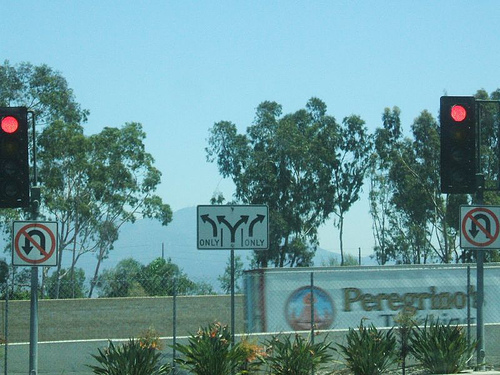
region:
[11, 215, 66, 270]
No u turn sign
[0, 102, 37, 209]
A red stop light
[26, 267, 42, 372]
Metal sign post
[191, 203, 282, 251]
Sign with four direction arrows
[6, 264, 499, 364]
A chain link fence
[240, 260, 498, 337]
A white tractor trailer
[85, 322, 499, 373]
Five shrubs in front of a fence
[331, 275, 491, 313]
The word Peregrino's on a trailer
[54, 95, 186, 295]
Green trees on the other side of the road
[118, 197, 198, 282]
Mountains in the far distance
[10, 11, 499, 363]
stoplights and street signs by wall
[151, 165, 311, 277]
street sign with arrows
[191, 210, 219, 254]
left arrow on sign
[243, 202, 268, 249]
right arrow on sign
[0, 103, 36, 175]
traffic light with red light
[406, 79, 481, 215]
red light on traffic light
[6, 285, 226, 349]
wall behind the street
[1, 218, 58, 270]
no u turn sign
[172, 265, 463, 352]
sign on a wall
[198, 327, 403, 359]
plants near the road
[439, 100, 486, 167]
There is a red stoplight that is on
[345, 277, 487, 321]
This sign reads "Peregrino's" on the side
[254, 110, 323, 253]
There is a large green tree in the distance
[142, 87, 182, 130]
The sky is a light blue color and is lovely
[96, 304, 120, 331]
There is a concrete barrier that is in place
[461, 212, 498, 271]
There is a sign that says no U-turn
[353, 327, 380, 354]
There are green plants on the side of the raod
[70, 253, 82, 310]
There are tree trunks that are very grey in color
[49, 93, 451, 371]
This photo was taken in Montana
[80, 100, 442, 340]
This photo was taken with a telephoto lens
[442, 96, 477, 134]
a red light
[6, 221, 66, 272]
a no U-turn sign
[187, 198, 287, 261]
a black and white turning lane sign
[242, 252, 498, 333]
a white truck on the road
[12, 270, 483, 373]
a chain link fence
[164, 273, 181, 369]
a metal support pole in a fence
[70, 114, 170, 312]
a tree by the side of the road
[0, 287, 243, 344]
a concrete wall by a roadway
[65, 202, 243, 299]
a mountain in the distance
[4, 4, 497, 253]
a pale blue sky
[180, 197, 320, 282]
road sign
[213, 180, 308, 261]
road sign